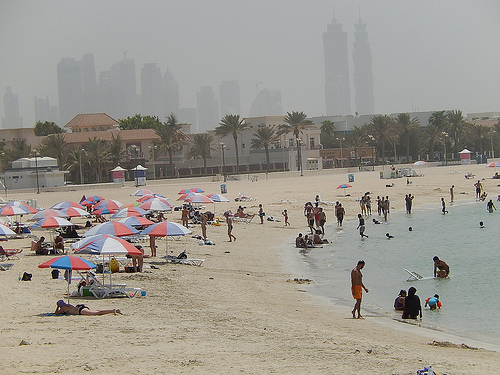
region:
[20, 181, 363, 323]
people on the beach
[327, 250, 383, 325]
person on the beach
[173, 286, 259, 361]
dirt on the ground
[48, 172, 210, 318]
umbrellas on the ground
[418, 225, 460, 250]
water next to people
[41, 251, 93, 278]
colorful umbrella above the person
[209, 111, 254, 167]
palm tree in the background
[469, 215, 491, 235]
head of the person in the water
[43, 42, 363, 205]
buildings in the background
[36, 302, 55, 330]
shadow on the sand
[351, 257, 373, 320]
A man in orange shorts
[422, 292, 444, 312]
A child wearing red floaties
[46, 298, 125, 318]
A woman lying on her stomach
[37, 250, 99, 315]
A red and blue umbrella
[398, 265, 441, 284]
A lounge chair in the water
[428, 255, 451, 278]
A person crouching in the water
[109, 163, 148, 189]
Small buildings in the distance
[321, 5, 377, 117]
Two tall skyscrapers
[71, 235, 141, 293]
A red white and blue umbrella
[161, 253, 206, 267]
An empty white lounge chair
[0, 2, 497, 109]
hazy gray daytime sky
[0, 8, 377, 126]
city buildings behind haze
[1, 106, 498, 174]
buildings and palm trees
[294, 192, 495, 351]
people in shallow water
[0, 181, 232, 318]
cluster of beach umbrellas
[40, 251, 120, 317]
person lying under umbrella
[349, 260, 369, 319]
man in orange swim trunks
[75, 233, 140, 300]
white lounge chairs under umbrella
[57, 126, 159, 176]
building with red roof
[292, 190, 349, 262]
people on edge of water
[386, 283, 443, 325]
Kids play in the water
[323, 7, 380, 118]
Two skyscrapers stand next to each other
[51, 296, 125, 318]
A person sunbathes on the beach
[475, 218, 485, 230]
A person swims in the water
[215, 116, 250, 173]
A single palm tree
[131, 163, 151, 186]
A blue beach pergola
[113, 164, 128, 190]
A red beach pergola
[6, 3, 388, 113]
City buildings in the fog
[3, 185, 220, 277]
A cluster of beach umbrellas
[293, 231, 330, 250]
People at the edge of the water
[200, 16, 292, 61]
this is the sky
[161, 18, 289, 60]
the sky is foggy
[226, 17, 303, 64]
the fog is white in color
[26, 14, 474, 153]
these are some buildings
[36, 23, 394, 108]
the buildings are tall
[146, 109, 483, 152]
these are some trees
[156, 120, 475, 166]
the trees are tall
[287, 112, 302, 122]
the leaves are green in color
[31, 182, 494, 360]
this is the beach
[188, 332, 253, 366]
the sand is brown in color